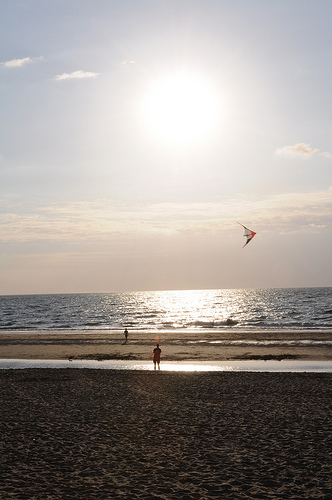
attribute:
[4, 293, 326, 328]
water — wavy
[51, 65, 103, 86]
clouds — small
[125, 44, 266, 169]
sun — blurred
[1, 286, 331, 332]
sea — blue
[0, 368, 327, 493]
sand — clumpy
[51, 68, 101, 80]
clouds — white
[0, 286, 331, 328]
waves — blue, ocean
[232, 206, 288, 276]
kite — soaring